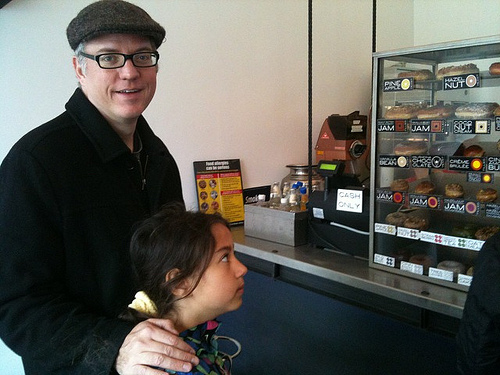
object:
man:
[1, 1, 202, 374]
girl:
[128, 211, 246, 374]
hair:
[115, 212, 231, 327]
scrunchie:
[128, 290, 159, 316]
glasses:
[98, 54, 125, 69]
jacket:
[1, 88, 187, 374]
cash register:
[295, 158, 369, 260]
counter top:
[225, 225, 467, 318]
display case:
[372, 43, 500, 288]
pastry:
[463, 144, 484, 157]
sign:
[192, 158, 245, 226]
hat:
[67, 3, 166, 51]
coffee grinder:
[315, 110, 368, 175]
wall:
[1, 0, 500, 375]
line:
[308, 1, 312, 164]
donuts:
[445, 182, 466, 198]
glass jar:
[289, 189, 298, 207]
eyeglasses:
[80, 50, 160, 70]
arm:
[1, 146, 131, 374]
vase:
[284, 163, 324, 207]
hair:
[74, 43, 87, 75]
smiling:
[111, 86, 151, 96]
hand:
[114, 317, 201, 375]